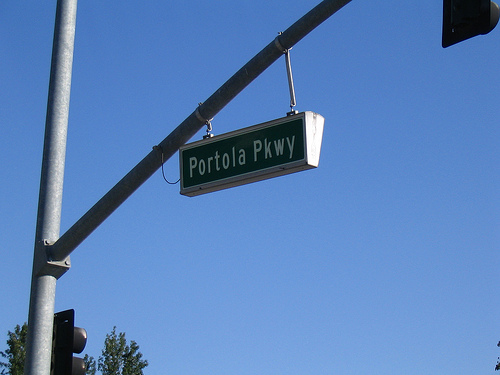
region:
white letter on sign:
[188, 154, 199, 180]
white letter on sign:
[198, 158, 206, 175]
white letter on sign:
[205, 153, 215, 175]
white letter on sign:
[212, 149, 221, 174]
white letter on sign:
[220, 151, 230, 170]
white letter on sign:
[229, 143, 236, 169]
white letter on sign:
[236, 147, 246, 165]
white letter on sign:
[252, 138, 262, 163]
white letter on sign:
[260, 135, 272, 160]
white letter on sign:
[269, 137, 285, 154]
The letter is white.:
[181, 153, 199, 184]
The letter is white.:
[195, 153, 207, 177]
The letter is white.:
[203, 149, 215, 177]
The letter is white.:
[211, 141, 223, 174]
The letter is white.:
[220, 148, 232, 173]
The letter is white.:
[229, 135, 237, 170]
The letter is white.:
[234, 143, 248, 170]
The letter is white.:
[251, 132, 265, 167]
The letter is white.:
[258, 133, 273, 162]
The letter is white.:
[270, 133, 287, 160]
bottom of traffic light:
[440, 0, 497, 46]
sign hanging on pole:
[178, 38, 324, 198]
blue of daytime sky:
[2, 5, 497, 370]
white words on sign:
[188, 133, 296, 178]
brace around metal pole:
[273, 32, 290, 56]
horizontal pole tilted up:
[62, 18, 322, 261]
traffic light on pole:
[27, 19, 88, 372]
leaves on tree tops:
[5, 322, 147, 373]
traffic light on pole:
[26, 307, 88, 373]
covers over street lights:
[72, 327, 89, 372]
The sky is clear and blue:
[151, 230, 477, 333]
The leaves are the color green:
[96, 330, 153, 370]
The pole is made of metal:
[12, 11, 93, 373]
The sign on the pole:
[153, 28, 336, 200]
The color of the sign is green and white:
[179, 118, 318, 191]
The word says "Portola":
[180, 143, 249, 180]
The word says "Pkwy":
[246, 130, 299, 164]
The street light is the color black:
[42, 300, 107, 371]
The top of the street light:
[52, 300, 92, 353]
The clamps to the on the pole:
[183, 23, 317, 142]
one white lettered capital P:
[185, 154, 198, 179]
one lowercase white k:
[261, 136, 275, 161]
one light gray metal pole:
[30, 5, 82, 374]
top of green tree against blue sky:
[97, 318, 154, 373]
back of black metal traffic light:
[53, 308, 95, 373]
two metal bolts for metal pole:
[41, 233, 72, 274]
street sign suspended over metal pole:
[101, 34, 356, 199]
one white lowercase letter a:
[237, 146, 247, 168]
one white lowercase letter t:
[212, 148, 222, 173]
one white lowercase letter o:
[196, 158, 206, 180]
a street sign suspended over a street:
[179, 109, 322, 195]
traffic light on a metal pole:
[51, 307, 87, 374]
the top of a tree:
[100, 323, 147, 373]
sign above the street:
[131, 85, 344, 209]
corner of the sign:
[285, 131, 348, 182]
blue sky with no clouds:
[233, 196, 389, 308]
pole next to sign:
[41, 146, 186, 258]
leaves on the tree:
[96, 310, 163, 367]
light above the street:
[408, 10, 498, 57]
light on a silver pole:
[32, 290, 109, 374]